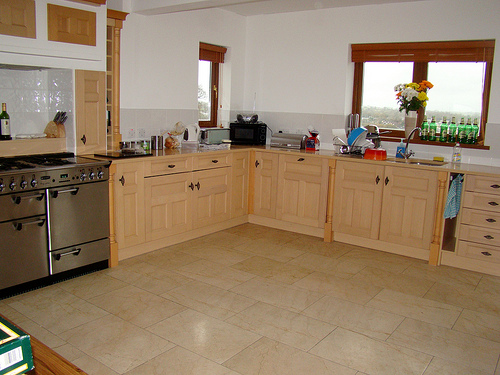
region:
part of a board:
[334, 183, 354, 208]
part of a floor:
[218, 250, 255, 292]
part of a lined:
[235, 300, 265, 327]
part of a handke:
[375, 172, 398, 200]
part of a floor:
[243, 253, 290, 303]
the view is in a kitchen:
[96, 71, 449, 193]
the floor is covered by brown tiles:
[241, 243, 404, 359]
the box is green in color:
[3, 325, 40, 370]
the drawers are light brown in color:
[152, 165, 240, 208]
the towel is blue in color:
[445, 175, 474, 220]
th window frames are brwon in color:
[348, 38, 477, 76]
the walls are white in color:
[243, 19, 295, 76]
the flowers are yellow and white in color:
[393, 78, 435, 107]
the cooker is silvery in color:
[49, 188, 112, 238]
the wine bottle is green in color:
[2, 103, 13, 138]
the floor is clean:
[188, 240, 430, 337]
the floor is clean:
[144, 271, 341, 365]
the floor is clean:
[185, 280, 362, 342]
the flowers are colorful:
[382, 75, 436, 112]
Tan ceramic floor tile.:
[8, 221, 496, 372]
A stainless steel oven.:
[0, 150, 112, 301]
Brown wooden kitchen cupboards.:
[72, 70, 498, 280]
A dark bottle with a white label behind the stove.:
[0, 97, 13, 140]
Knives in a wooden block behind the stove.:
[40, 110, 69, 138]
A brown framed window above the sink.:
[347, 37, 495, 148]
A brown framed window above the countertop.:
[195, 41, 228, 123]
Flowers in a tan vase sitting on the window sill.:
[391, 79, 434, 138]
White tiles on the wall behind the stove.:
[0, 67, 76, 150]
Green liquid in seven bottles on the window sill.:
[419, 115, 479, 145]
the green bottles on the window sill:
[421, 115, 478, 144]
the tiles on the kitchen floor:
[0, 223, 497, 373]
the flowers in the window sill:
[393, 80, 435, 137]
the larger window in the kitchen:
[344, 39, 494, 146]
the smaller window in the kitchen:
[197, 40, 226, 127]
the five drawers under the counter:
[455, 172, 499, 263]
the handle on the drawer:
[480, 250, 492, 257]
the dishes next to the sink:
[330, 124, 390, 160]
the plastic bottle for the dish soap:
[451, 141, 461, 163]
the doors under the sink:
[331, 159, 438, 249]